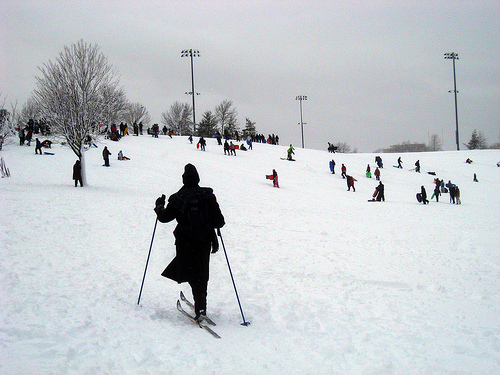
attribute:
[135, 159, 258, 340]
person — skiing, skier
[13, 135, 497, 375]
hill — snowy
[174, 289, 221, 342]
skis — pair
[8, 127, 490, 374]
snow — white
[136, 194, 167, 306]
ski pole — black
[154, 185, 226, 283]
coat — long, black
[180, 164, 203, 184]
cap — woolen, black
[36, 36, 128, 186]
tree — snow covered, short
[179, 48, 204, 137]
lamp post — metallic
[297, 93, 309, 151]
lamp post — metallic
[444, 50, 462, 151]
lamp post — metallic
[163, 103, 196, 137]
tree — bare, snow covered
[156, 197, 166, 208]
glove — black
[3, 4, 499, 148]
sky — gray, overhead, cloudy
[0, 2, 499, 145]
clouds — white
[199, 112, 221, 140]
tree — leafy